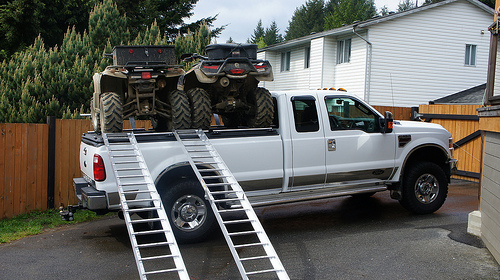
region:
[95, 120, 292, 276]
Two aluminum ramps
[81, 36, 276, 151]
Two ATVs on the back of a truck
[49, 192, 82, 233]
A trailer hitch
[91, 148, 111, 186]
A tail light on the back of a truck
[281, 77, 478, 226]
A white truck cab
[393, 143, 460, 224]
A tire on a truck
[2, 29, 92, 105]
The tops of pine trees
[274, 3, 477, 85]
A white house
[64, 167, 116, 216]
The back bumper of a truck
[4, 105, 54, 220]
A brown wooden fence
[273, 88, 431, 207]
this is a pickup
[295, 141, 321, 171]
the piockup is white in color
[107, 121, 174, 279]
this is a ladder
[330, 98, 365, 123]
this is the window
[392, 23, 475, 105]
this is a wall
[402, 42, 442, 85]
the wall is white in color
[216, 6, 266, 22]
this is the sky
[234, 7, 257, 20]
the sky is blue in color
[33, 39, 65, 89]
this is a tree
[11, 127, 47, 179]
this is a fence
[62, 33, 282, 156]
a couple of motorcycles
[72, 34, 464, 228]
a white truck with four wheelers in the back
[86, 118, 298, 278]
a silver ramp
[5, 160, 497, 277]
a gray parking lot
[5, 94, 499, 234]
tan fence on the side and front of truck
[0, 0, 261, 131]
a green bush next to truck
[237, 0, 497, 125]
a white building in the background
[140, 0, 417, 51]
a sky with clouds in it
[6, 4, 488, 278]
a scene happening during the day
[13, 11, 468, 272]
a scene outside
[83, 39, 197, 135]
A quad runner vechicle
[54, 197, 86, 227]
Trailer hitch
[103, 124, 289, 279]
Truck loading ramps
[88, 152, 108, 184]
Vehicle rear break and turn signal light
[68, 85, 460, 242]
White pick-up truck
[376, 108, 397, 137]
Truck wide view mirrors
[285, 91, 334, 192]
Extended cab area of truck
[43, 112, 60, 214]
Fence post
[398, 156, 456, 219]
Aluminum alloy truck wheel with tire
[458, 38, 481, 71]
Slider house window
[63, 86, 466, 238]
a white pickup truck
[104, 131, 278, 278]
two white ramps coming off truck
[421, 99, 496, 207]
A wooden gate with metal trim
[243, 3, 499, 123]
A white house beyond fence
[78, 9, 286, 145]
two 4 wheelers in a truck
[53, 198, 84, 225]
A hitch on the back of the truck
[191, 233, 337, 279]
Shadow of the ramps on the ground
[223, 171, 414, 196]
Silver stripe on side of truck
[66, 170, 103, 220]
Black and silver bumper on truck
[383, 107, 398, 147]
Black mirror with turning indicator